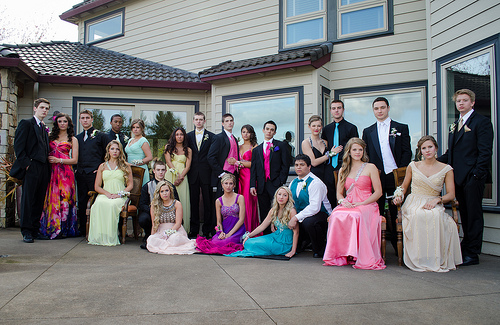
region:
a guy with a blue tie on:
[309, 84, 353, 174]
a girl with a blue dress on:
[249, 185, 306, 260]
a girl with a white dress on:
[394, 126, 466, 290]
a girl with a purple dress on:
[209, 172, 249, 249]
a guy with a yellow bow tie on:
[182, 93, 224, 200]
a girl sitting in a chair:
[84, 125, 149, 241]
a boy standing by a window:
[438, 26, 498, 189]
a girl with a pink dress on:
[314, 128, 401, 244]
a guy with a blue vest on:
[289, 148, 334, 238]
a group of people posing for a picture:
[26, 75, 446, 255]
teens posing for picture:
[4, 65, 492, 285]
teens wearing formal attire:
[8, 78, 498, 273]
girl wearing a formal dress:
[239, 179, 302, 266]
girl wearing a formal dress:
[196, 168, 250, 262]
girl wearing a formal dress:
[77, 136, 139, 245]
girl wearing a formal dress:
[45, 106, 84, 241]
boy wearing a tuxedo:
[76, 106, 108, 211]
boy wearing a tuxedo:
[7, 91, 57, 251]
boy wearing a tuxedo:
[365, 89, 422, 224]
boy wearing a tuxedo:
[440, 89, 498, 268]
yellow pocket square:
[462, 123, 469, 130]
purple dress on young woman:
[195, 193, 246, 256]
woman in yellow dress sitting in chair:
[86, 140, 135, 246]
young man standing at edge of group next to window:
[432, 87, 489, 267]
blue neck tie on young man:
[330, 120, 340, 168]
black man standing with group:
[102, 114, 132, 163]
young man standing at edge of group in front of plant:
[6, 98, 49, 245]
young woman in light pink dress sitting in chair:
[317, 140, 386, 270]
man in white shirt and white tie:
[362, 91, 414, 263]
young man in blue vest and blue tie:
[283, 153, 328, 260]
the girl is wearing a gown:
[322, 175, 390, 270]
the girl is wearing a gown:
[403, 163, 461, 270]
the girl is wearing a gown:
[92, 167, 132, 247]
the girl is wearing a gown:
[236, 143, 256, 225]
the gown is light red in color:
[328, 177, 382, 269]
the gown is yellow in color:
[402, 160, 459, 277]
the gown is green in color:
[90, 168, 127, 243]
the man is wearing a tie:
[328, 123, 341, 171]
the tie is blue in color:
[331, 123, 340, 168]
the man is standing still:
[443, 90, 489, 262]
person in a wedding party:
[385, 126, 465, 282]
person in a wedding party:
[318, 138, 383, 275]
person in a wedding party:
[219, 183, 303, 265]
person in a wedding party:
[197, 171, 252, 255]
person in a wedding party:
[140, 178, 201, 253]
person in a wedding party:
[82, 138, 137, 251]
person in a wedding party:
[39, 112, 79, 240]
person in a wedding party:
[435, 82, 498, 275]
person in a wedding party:
[357, 88, 417, 277]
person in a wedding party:
[320, 97, 359, 181]